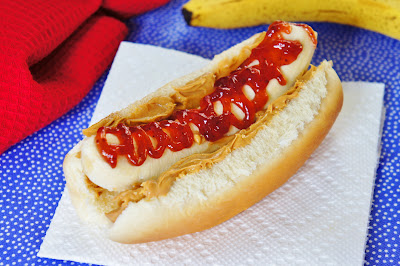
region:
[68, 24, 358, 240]
a hot dog bun is part of the meal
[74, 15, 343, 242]
a banana is in a hot dog bun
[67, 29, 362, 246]
the sanwich is on a napkin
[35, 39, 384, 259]
the napkin is white in color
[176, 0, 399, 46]
a banana is on the table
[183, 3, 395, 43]
the banana is yellow in color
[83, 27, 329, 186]
the banana has been peeled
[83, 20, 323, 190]
the banana is white in color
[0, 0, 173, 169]
a towel is on the table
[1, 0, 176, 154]
the towel is red in color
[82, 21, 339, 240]
banana on the bun.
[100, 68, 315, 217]
Brown peanut butter on the bun.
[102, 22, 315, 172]
jelly on the banana.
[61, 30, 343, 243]
Bun under the banana.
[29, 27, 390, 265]
White napkin under the food.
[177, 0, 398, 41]
Yellow banana on the table cloth.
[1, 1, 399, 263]
Blue and white table cloth in the background.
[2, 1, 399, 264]
White stars on the tablecloth.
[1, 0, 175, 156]
Red towel on the tablecloth.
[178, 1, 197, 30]
Brown tip on the banana.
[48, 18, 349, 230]
this is a banana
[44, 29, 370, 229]
the banana looks like a hotdog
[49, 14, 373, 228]
this looks like a hot dog sandwich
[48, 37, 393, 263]
this is not a hot dog sandwich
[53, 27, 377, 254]
this is a peanut butter, banana, and jelly sandwich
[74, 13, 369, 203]
there is jelly on the banana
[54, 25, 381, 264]
peanut butter is spread on the bread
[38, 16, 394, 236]
the sandwich is on a napkin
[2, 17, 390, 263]
the paper towel is folded into a square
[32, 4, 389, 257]
a sandwich on a paper towel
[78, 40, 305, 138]
the jelly is red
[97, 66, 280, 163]
the jelly is red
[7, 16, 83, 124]
the towel is red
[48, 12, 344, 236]
a banana on a hot dog bun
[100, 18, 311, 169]
the banana has some jelly topping on it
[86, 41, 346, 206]
the banana is laying on a bed of peanut butter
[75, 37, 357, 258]
the hot dog bun is sitting on a napkin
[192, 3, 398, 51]
a banana is in the background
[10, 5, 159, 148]
a red towel is to the left of the hot dog bun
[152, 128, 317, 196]
the hot dog bun is made up of bread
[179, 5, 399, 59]
some fruit lay in the background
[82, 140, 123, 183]
the banana is white in color